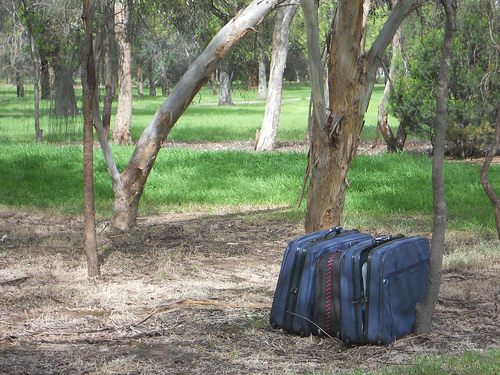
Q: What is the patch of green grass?
A: Large.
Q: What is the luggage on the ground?
A: Blue and black.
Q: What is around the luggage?
A: Area of dead grass, branches and leaves.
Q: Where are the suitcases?
A: On the ground.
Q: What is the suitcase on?
A: Dirt.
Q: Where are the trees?
A: Around the suitcases.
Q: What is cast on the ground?
A: Shadows.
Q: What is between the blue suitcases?
A: A black and red suitcase.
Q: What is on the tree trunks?
A: Bark.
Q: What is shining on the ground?
A: Sunlight.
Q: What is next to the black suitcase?
A: Blue suitcases.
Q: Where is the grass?
A: Next to the dirt.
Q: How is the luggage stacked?
A: Horizontally.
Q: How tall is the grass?
A: Short.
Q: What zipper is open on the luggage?
A: Main.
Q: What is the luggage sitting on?
A: Dirt ground.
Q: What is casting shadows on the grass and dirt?
A: Trees.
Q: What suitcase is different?
A: Middle.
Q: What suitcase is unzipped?
A: Farthest right.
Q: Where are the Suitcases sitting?
A: On dirt.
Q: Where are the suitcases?
A: Between trees.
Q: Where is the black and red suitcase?
A: Between blue suitcases.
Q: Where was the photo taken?
A: Wooded area.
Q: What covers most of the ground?
A: Grass.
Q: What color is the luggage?
A: Blue.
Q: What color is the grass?
A: Green.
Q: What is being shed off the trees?
A: Bark.